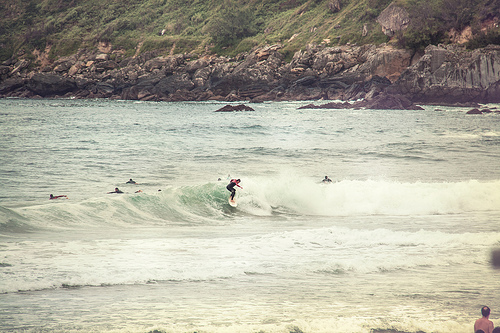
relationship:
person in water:
[126, 179, 137, 185] [1, 100, 499, 333]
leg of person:
[134, 190, 142, 193] [109, 188, 142, 194]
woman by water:
[494, 326, 499, 332] [1, 100, 499, 333]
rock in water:
[214, 105, 253, 112] [1, 100, 499, 333]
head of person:
[130, 178, 133, 182] [126, 179, 137, 185]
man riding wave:
[226, 179, 242, 202] [0, 179, 499, 232]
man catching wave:
[226, 179, 242, 202] [0, 179, 499, 232]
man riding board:
[226, 179, 242, 202] [229, 197, 237, 207]